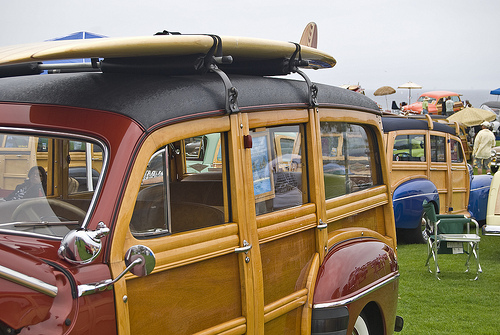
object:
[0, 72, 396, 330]
vehicle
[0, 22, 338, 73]
surfboard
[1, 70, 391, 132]
roof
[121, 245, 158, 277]
mirror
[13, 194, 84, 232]
wheel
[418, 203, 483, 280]
chair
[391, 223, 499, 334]
grass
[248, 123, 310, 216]
window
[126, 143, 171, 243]
window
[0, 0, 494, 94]
sky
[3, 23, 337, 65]
cream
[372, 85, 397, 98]
umbrellas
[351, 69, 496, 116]
distance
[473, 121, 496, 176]
man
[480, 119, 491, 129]
cap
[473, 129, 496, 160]
white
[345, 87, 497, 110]
ocean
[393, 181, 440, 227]
blue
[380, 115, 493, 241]
woody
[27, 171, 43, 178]
glasses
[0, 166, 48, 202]
woman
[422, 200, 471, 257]
green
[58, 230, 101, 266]
mirror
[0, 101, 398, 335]
red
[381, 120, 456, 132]
black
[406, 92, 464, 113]
car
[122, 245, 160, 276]
silver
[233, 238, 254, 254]
handle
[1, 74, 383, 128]
leather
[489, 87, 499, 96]
umbrella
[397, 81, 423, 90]
umbrella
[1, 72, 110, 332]
front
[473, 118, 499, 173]
person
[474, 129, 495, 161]
jacket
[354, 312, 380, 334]
wheel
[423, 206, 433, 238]
wheel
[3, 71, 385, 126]
top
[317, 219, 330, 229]
silver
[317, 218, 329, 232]
handle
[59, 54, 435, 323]
car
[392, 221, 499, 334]
ground